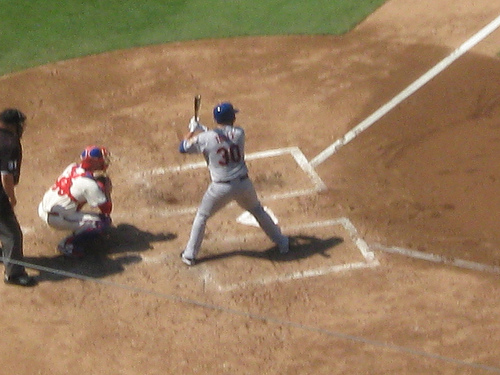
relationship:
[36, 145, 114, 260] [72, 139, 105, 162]
baseball catcher wearing hat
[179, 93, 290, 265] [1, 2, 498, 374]
baseball player playing on field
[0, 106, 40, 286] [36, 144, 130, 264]
athlete behind catcher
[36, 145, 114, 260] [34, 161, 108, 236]
baseball catcher wearing uniform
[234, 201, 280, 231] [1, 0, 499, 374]
plate on field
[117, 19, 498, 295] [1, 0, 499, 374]
lines on field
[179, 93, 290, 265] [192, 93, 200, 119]
baseball player with bat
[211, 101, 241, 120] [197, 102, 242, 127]
baseball hat on player's head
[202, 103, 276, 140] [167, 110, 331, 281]
hat on player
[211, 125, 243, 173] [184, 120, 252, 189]
red print on baseball jersey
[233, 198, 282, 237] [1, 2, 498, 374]
base on field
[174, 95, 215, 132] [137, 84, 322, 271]
bat with player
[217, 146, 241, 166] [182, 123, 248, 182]
number 30 on baseball jersey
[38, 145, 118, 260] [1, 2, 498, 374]
baseball catcher on field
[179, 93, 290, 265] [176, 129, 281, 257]
baseball player wearing uniform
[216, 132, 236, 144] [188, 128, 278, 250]
writing on uniform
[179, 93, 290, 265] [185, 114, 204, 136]
baseball player wearing gloves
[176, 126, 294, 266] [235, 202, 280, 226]
player standing base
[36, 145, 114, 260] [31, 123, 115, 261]
baseball catcher wearing uniform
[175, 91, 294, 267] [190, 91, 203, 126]
baseball player prepares to swing bat